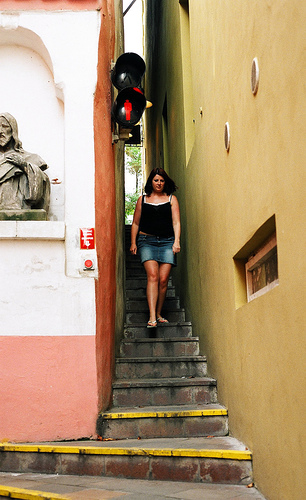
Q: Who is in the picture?
A: A lady is in the picture.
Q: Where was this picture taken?
A: It was taken outside on a stairway.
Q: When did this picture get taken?
A: It was taken in the day time.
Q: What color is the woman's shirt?
A: Her shirt is black.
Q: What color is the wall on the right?
A: The wall is brown.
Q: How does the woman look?
A: She looks calm and attractive.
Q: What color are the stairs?
A: The stairs are grey.